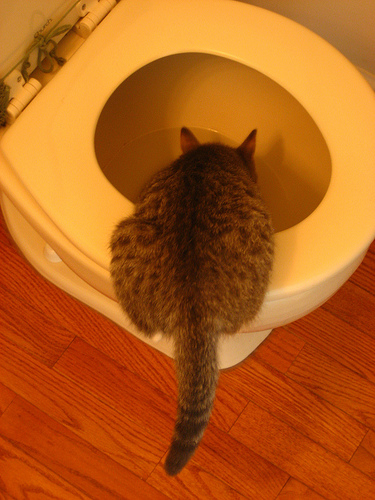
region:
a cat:
[91, 97, 242, 418]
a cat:
[196, 143, 267, 452]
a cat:
[121, 137, 271, 498]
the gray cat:
[113, 118, 270, 478]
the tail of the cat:
[153, 332, 224, 478]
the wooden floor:
[17, 340, 139, 488]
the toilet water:
[128, 136, 166, 169]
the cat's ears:
[174, 124, 263, 159]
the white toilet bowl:
[8, 1, 373, 364]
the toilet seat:
[22, 0, 372, 268]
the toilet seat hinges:
[9, 0, 114, 119]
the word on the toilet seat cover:
[27, 17, 53, 36]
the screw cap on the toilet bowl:
[37, 241, 64, 264]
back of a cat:
[179, 182, 221, 251]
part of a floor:
[265, 414, 301, 445]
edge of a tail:
[194, 418, 206, 442]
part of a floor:
[219, 436, 261, 477]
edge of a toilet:
[266, 295, 298, 325]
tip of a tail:
[156, 451, 178, 498]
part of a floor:
[227, 417, 277, 480]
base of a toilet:
[219, 347, 257, 378]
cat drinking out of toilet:
[132, 111, 297, 261]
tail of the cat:
[121, 358, 252, 499]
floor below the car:
[45, 369, 106, 414]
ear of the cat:
[232, 120, 267, 152]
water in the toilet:
[115, 122, 160, 168]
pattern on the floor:
[47, 367, 122, 457]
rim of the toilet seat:
[270, 20, 345, 80]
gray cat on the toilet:
[156, 158, 233, 239]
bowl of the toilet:
[172, 75, 224, 105]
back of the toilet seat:
[15, 7, 60, 52]